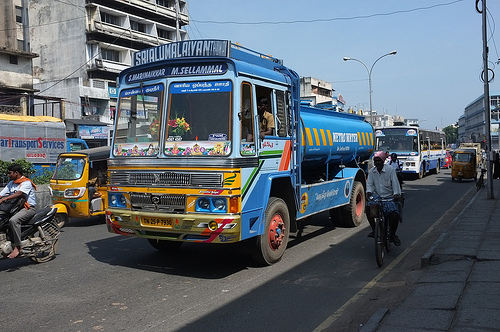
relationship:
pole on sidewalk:
[480, 6, 494, 200] [319, 162, 498, 329]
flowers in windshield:
[147, 116, 194, 138] [113, 81, 230, 159]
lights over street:
[339, 39, 407, 143] [26, 254, 359, 329]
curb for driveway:
[356, 184, 484, 329] [377, 262, 493, 309]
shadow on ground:
[99, 240, 251, 279] [3, 162, 495, 330]